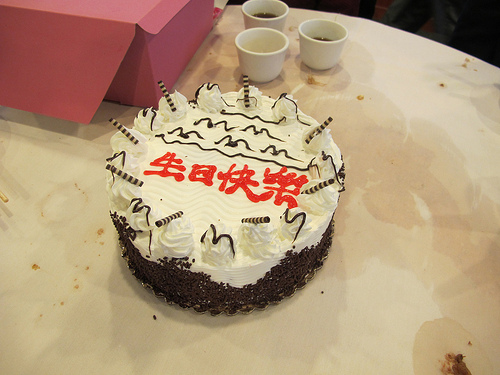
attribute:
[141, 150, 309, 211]
frosting — red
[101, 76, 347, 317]
cake — dark brown, white, chocolate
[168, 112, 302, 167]
icing — brown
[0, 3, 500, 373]
tablecloth — white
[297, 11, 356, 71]
cup — white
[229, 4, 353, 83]
cups — white, small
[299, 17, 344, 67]
tea cup — white, small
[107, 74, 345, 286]
icing — white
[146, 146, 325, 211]
characters — red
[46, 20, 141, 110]
box — pink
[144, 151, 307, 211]
writing — red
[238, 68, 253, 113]
biscuit — striped, black, white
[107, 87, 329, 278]
icing — white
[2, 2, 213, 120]
box — pink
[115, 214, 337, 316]
cake part — brown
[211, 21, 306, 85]
cup — small, white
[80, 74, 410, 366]
cake — brown and white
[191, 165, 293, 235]
icing — white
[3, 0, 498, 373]
table — white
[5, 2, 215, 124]
cardboard box — matte red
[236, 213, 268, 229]
biscuit stick — black, white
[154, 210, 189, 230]
biscuit stick — black, white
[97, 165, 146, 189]
biscuit stick — black, white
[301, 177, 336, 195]
candle — black, white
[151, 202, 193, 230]
stick — white, black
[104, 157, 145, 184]
stick — white, black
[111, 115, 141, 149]
stick — white, black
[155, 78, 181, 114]
stick — white, black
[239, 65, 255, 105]
stick — white, black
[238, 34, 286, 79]
bowl — tiny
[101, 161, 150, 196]
stick — striped, black, white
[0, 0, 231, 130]
box — pink, opened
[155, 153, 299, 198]
writing — red, asian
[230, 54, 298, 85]
cups — white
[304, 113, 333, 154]
biscuit stick — black, white